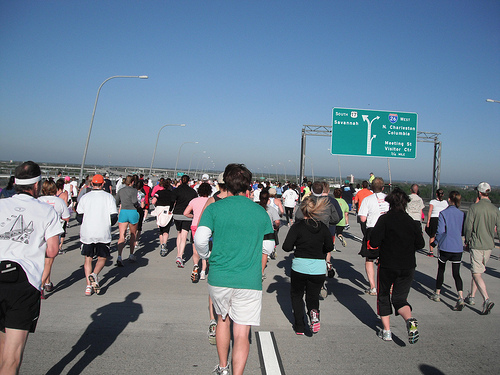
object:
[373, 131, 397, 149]
street sign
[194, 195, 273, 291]
shirt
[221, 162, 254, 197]
head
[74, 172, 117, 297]
jogger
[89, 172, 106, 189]
head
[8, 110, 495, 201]
cloud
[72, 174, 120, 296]
person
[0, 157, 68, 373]
person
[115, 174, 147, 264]
person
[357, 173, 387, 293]
person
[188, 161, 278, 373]
person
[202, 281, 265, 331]
tan shorts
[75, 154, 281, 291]
wildflowers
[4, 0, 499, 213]
sky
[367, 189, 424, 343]
person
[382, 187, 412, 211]
head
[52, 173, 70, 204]
person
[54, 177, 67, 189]
head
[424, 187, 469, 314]
woman